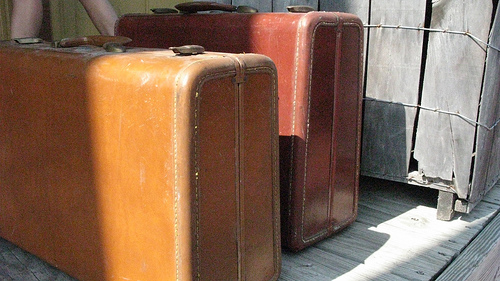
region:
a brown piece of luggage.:
[0, 32, 289, 276]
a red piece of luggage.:
[104, 0, 382, 249]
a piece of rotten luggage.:
[363, 6, 494, 243]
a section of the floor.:
[274, 198, 496, 278]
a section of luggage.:
[0, 0, 164, 55]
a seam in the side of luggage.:
[221, 58, 260, 278]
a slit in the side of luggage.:
[325, 22, 345, 247]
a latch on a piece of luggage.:
[133, 28, 213, 99]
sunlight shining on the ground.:
[340, 182, 475, 279]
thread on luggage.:
[173, 63, 203, 279]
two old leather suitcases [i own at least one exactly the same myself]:
[0, 0, 371, 278]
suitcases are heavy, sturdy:
[0, 0, 385, 277]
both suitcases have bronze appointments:
[5, 1, 315, 66]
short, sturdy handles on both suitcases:
[46, 0, 248, 52]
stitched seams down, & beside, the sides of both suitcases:
[153, 8, 375, 278]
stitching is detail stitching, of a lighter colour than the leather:
[163, 8, 375, 278]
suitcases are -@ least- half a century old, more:
[0, 0, 370, 279]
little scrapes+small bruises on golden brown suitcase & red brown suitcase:
[0, 12, 366, 279]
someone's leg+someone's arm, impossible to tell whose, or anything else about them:
[0, 0, 127, 47]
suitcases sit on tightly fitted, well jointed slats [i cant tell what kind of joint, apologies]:
[1, 171, 498, 278]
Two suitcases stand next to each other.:
[121, 5, 369, 218]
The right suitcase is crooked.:
[275, 41, 375, 265]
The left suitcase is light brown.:
[71, 52, 216, 212]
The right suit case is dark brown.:
[285, 27, 370, 197]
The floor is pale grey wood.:
[375, 210, 430, 276]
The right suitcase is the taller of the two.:
[95, 5, 370, 235]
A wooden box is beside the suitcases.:
[380, 49, 491, 195]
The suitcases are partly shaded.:
[10, 7, 272, 77]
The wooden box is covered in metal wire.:
[371, 16, 476, 43]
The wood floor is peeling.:
[372, 226, 427, 279]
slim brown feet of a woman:
[5, 0, 122, 37]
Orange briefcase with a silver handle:
[13, 35, 264, 277]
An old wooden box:
[378, 16, 486, 220]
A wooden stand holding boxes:
[326, 198, 498, 278]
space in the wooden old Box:
[409, 26, 434, 178]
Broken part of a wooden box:
[411, 143, 473, 226]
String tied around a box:
[366, 91, 496, 138]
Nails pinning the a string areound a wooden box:
[437, 28, 481, 40]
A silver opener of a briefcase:
[173, 44, 210, 56]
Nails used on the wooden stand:
[403, 219, 487, 275]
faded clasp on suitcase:
[168, 39, 204, 56]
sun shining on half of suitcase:
[88, 42, 284, 279]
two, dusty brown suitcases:
[2, 2, 372, 277]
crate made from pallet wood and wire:
[235, 0, 498, 221]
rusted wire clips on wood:
[363, 17, 490, 52]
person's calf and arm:
[7, 0, 127, 50]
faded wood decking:
[285, 192, 498, 278]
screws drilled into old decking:
[396, 192, 498, 279]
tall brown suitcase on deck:
[113, 2, 369, 257]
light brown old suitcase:
[3, 25, 280, 279]